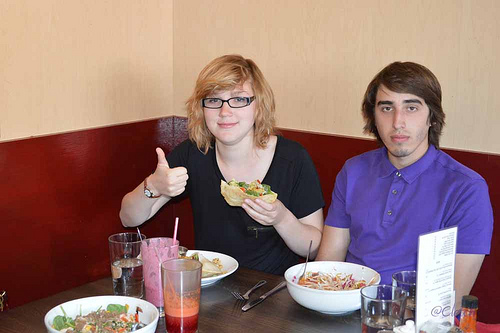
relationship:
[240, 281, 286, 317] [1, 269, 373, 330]
knife on table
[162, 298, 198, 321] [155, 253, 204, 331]
juice on glass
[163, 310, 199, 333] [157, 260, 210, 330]
juice in glass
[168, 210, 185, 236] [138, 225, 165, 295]
straw in glass